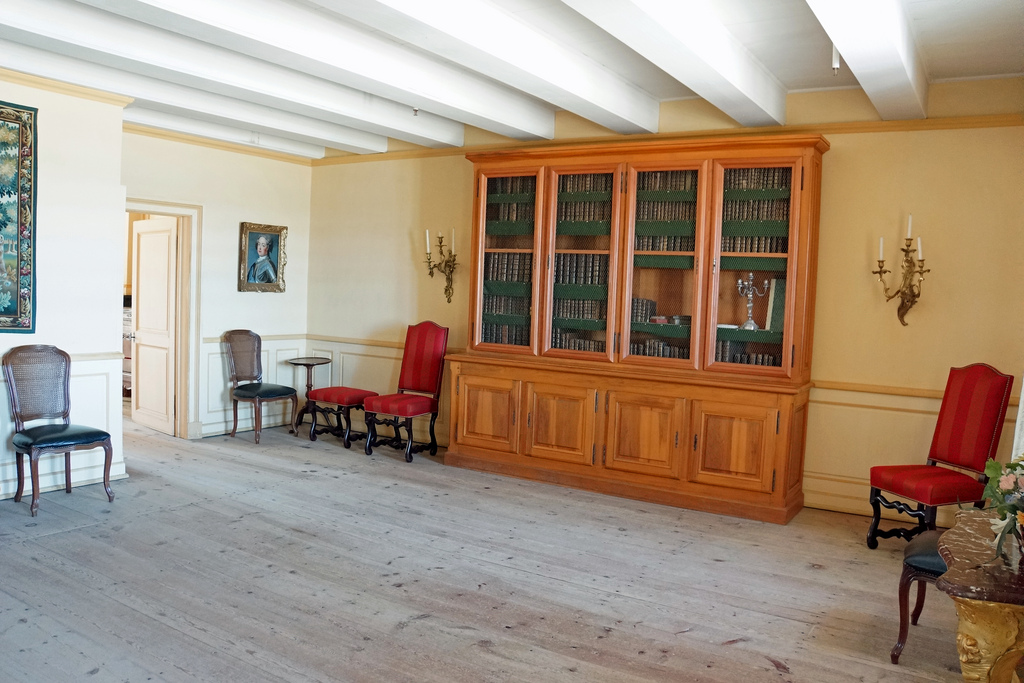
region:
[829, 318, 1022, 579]
red chair in corner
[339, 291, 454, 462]
red chair next to wall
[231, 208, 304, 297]
portrait on the wall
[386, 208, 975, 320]
a pair of sconces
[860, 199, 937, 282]
candles on the sconces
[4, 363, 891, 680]
the floor is wooden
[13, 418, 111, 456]
leather seat on chair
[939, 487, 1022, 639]
mantle on the side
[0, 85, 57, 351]
side of a picture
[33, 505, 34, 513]
leg of the chair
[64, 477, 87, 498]
leg of the chair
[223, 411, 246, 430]
leg of the chair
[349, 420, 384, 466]
leg of the chair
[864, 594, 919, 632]
leg of the chair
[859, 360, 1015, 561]
chair is red and black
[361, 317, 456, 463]
chair is red and black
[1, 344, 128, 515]
chair is against wall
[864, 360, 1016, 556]
chair is in the corner of the room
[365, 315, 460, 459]
chair is against the wall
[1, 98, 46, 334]
picture is hanging on the wall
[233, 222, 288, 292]
picture is hanging on the wall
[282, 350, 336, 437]
table sits in corner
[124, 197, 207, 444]
door is open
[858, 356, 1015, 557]
Red upholstered chair with straight back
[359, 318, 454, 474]
Red upholstered chair with straight back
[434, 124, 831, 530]
Wooden display cabinet holding books on shelves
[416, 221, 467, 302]
Wall mounted candelabra lighting sconces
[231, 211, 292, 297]
Wall mounted rectangular painting of a man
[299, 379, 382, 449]
Red upholstered footrest with wooden legs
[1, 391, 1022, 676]
Wooden planked flooring with natural finish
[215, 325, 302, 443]
Wooden chair with dark leather padded seat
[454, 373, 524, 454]
A door for a cabinet.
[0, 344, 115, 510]
the chair is against the wall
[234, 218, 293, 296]
the painting is hanging on the wall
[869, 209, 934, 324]
the candle holder is hanging on the wall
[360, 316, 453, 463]
the chair has red upholstery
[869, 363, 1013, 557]
the chair has red upholstery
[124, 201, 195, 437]
the door is in an open position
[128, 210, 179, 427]
the door is painted white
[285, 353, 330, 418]
the table is made of wood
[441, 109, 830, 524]
ornate candle holder in wooden bookcase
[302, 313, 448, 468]
red and black stool next to red and black chair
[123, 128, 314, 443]
gilt framed portrait on yellow wall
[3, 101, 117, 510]
wood and black chair underneath a tapestry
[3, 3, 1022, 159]
white beams across the ceiling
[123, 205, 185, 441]
the door is open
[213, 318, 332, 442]
black and wooden chair next to small wooden table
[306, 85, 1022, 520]
wainscoating on yellow wall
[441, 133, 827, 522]
glass doors on wooden bookcase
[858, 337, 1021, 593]
red fabric chair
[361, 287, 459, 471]
red fabric chair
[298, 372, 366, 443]
red fabric ottoman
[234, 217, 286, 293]
painting portrait of man on wall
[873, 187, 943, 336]
gold candle holder on wall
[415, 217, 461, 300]
gold candle holder on wall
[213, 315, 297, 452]
brown and black chair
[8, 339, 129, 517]
brown and black chair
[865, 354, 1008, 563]
chair is black with red cushions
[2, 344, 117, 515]
chair is wooden with a black leather seat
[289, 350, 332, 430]
small accent table is round